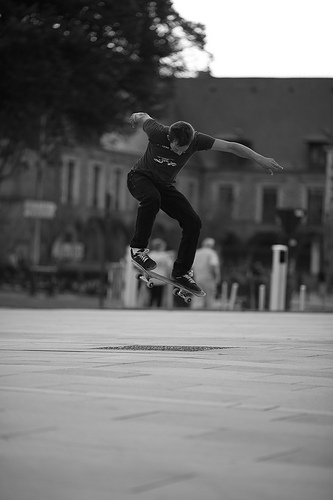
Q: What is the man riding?
A: Skateboard.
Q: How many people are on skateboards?
A: One.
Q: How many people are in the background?
A: Two.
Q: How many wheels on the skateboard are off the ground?
A: Four.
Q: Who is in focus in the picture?
A: Skateboarder.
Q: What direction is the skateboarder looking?
A: Down.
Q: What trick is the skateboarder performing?
A: Jump.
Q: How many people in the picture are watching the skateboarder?
A: Zero.